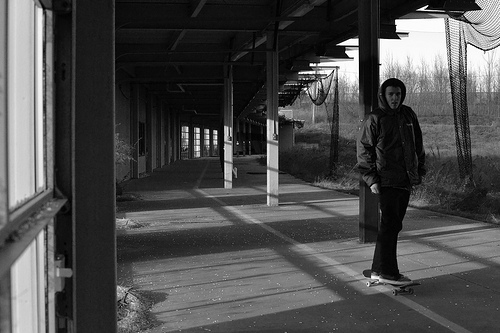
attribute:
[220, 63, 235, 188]
beam — support, metal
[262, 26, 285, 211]
beam — support, metal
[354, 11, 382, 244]
beam — support, metal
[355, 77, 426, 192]
jacket — long sleeve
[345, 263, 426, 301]
skateboard — rolling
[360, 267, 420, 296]
skateboard — black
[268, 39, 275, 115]
post — white, wooden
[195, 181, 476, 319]
line — white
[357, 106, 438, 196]
jacket — black, hooded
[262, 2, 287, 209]
beam — metal, support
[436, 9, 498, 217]
net — hanging 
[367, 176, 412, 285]
pants — black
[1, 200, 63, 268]
window sill — dirty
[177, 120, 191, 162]
window — small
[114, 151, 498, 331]
platform — long, concrete, gray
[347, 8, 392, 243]
beam — metal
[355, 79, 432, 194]
jacket — small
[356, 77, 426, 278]
man — skating, tall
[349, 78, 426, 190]
jacket — black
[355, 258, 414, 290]
shoes — vans brand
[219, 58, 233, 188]
wooden post — white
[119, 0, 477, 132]
roof — dark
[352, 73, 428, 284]
man — small, tall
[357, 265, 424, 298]
skateboard — small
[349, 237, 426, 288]
shoes — sneaker, white, black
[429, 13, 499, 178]
net — small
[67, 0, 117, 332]
beam — metal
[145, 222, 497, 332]
ground — boarded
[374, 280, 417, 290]
sole — white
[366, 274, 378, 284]
sole — white